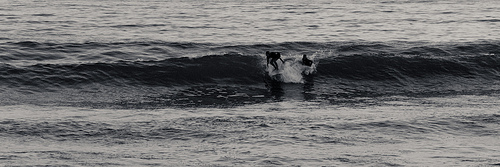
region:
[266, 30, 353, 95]
2 men on surfboards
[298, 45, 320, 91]
man on right riding surfboard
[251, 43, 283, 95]
man on left on surfboard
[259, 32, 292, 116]
man bending over riding surfboard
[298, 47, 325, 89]
man sitting down on surfboard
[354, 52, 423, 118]
small wave surfboard is on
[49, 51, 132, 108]
wave is dark and smooth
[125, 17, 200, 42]
ripples in water in background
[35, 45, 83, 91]
larger ripple in water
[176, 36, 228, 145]
medium wave in ocean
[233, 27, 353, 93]
Two people are in the ocean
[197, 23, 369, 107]
The people are surfing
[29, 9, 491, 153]
The day is not particularly sunny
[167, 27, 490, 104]
The waves are medium-sized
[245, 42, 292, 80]
This man's feet are on the surfboard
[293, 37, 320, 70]
The man is on his belly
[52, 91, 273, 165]
The water is blue and pretty dark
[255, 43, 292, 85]
Both of this man's hands are at his side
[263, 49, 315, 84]
The wave is white in the middle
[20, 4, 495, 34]
The water is mostly calm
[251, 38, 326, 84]
two people in the water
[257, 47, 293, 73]
person crouching down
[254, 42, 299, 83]
person on a surfboard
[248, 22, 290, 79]
person surfing a wave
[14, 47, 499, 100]
a pretty small wave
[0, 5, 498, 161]
body of water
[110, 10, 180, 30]
small ripples in the water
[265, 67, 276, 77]
pointy tip of the surfboard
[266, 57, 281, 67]
knees are bent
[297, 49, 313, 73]
laying on the board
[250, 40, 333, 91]
There are two surfers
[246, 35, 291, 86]
The surfer is crouching down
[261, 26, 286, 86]
The person is on top of a board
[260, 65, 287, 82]
The board is white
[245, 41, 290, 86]
The surfer is wearing a black wet suit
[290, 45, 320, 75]
The surfer is lying on their surfboard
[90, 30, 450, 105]
The wave is starting to break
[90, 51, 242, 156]
The water is dark blue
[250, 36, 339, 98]
The surfers are on a wave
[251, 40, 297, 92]
The surfboard breaks through the water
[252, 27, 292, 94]
Surfer on a surfboard.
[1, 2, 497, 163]
The water is wavy.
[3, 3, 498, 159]
The water is zealous.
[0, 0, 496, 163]
The water is engaging.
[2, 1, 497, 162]
The water is swift.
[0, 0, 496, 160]
The water is strong.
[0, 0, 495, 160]
The water is rambunctious.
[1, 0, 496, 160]
The water is forceful.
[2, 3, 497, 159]
The water is buoyant.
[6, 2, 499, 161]
The water is aggressive.